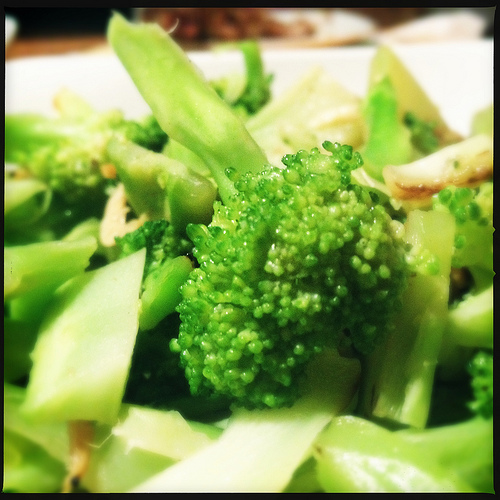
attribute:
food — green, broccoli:
[105, 17, 400, 389]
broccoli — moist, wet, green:
[103, 17, 271, 182]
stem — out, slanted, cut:
[107, 10, 271, 178]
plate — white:
[13, 41, 500, 130]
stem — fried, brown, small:
[389, 128, 499, 197]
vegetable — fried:
[387, 103, 495, 266]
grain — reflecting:
[222, 178, 377, 301]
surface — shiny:
[55, 72, 464, 465]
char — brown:
[403, 169, 490, 193]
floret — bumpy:
[103, 13, 402, 395]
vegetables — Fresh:
[61, 250, 271, 408]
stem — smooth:
[21, 250, 149, 433]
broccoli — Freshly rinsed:
[173, 140, 411, 412]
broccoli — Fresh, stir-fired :
[155, 105, 395, 370]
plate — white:
[0, 39, 490, 143]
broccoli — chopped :
[2, 13, 492, 492]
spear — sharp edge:
[19, 246, 155, 423]